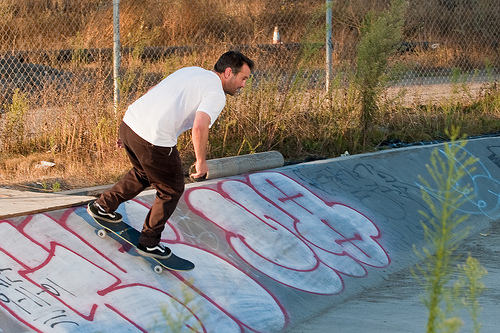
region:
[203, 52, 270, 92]
head of a person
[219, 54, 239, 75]
ear of a person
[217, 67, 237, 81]
an ear of a person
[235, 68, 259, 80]
eye of a person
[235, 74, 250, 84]
an eye of a person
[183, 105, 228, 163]
arm of a person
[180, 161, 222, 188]
hand of a person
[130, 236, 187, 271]
feet of a person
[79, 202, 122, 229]
feet of a person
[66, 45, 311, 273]
person on a skateboard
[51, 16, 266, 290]
a man skateboarding down a ramp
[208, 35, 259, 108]
a man with a short beard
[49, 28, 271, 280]
a man riding a skateboard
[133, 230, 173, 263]
a white and black tennis shoe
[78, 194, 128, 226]
a white and black tennis shoe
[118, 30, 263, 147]
a man wearing a white t-shirt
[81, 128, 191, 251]
the legs of a man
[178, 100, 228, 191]
the arm of a man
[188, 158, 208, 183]
the hand of a man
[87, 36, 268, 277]
This is a person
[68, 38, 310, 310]
This is a person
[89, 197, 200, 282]
Man on a board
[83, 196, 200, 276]
Man is on a board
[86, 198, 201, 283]
Man on a skateboard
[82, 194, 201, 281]
Man is on a skateboard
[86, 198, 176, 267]
Man wearing shoes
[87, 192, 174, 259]
Man is wearing shoes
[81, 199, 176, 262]
Man wearing black and white shoes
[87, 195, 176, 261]
Man is wearing black and white shoes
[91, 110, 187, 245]
Man wearing brown pants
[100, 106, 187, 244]
Man is wearing brown pants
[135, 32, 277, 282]
man on a skateboard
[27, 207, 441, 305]
graffiti on pavement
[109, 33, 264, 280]
man in white shirt riding a skateboard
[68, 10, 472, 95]
chain link fence in background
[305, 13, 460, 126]
green shrubs on the ground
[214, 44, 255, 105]
man with dark hair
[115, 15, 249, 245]
man wearing brown pants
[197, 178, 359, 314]
red and white grafitit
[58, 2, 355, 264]
man riding skateboard down slope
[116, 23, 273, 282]
man wearing black and white shoes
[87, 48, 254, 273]
A man standing on a skateboard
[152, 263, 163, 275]
Wheels on a skateboard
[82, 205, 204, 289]
The skateboard on the ramp.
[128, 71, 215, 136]
The shirt is white.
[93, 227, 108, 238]
Wheels on the skateboard.